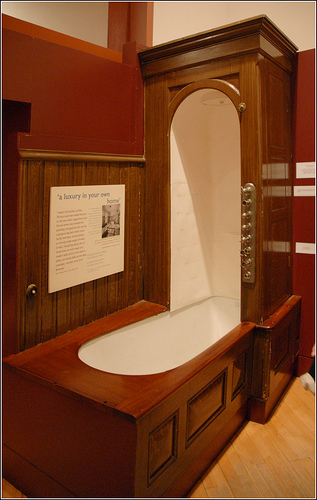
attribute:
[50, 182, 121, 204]
words — present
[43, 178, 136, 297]
sign — present, white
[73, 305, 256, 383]
bathtub — white, wood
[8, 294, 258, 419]
wood — reddish orange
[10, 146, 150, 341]
wall — red, wooden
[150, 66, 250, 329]
shower — tall, brown, wooden, white, curved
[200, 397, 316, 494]
floor — wood, yellow, wooden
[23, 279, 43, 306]
knob — round, small, white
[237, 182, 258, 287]
nozzles — silver, long, grey, metal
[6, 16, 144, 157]
wall — red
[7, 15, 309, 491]
frame — large, brown, wooden